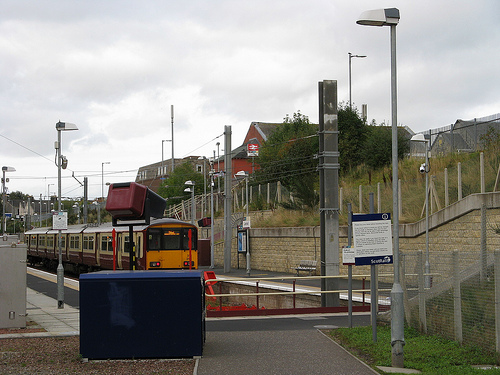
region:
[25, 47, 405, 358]
this is in a city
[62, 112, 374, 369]
this is a transit area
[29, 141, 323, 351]
this is a train stop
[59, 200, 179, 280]
this is a train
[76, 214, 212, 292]
the train is a passenger one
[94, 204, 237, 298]
the train front is orange and black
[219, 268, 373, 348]
this is a railing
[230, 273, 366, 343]
the railing is white and red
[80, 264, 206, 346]
this is a power box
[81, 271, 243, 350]
the electrical box is dark blue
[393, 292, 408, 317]
part f a post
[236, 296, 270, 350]
part of a shade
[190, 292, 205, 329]
edge of a box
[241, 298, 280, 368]
part of a floor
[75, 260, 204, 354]
a blue box on the ground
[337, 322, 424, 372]
grass in front of the fence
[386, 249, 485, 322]
a fence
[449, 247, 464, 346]
a wooden post on the fence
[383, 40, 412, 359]
a silver pole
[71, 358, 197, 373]
rocks next to the sidewalk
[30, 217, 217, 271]
a yellow train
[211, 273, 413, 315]
a red and white railing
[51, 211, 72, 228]
a sign on the pole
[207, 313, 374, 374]
the sidewalk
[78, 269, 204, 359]
the box is blue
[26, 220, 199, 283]
a train is driving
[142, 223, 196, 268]
front of train is orange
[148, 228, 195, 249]
front windows of train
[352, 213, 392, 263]
the sign is black and white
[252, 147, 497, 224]
hill full of weeds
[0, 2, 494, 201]
the sky is full of clouds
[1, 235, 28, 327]
the box is gray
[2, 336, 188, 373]
brown rocks on ground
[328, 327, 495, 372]
a patch of short grass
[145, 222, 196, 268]
the train is yellow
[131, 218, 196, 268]
a train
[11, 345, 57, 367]
the rocks on the ground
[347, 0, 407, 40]
a street light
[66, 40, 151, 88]
the clouds in the sky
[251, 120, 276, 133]
the roof on the building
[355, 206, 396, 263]
a blue and white sign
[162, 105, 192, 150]
a pole in the sky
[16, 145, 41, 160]
a power line in the sky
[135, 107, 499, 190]
the buildings on right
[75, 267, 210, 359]
a bin up front